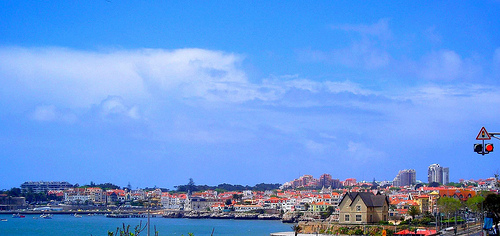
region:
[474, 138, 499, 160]
traffic light floating in the air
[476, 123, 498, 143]
traffic sign floating in the air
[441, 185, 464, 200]
red roof on old building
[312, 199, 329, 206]
red roof on old building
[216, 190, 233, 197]
red roof on old building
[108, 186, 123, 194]
red roof on old building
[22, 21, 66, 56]
white clouds in blue sky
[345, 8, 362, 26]
white clouds in blue sky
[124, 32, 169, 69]
white clouds in blue sky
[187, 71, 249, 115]
white clouds in blue sky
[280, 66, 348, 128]
white clouds in blue sky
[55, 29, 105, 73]
white clouds in blue sky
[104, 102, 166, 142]
white clouds in blue sky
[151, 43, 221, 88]
white clouds in blue sky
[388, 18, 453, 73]
white clouds in blue sky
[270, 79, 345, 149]
white clouds in blue sky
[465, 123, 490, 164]
sign on a pole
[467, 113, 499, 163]
sign on a metal pole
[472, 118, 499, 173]
pole with a sign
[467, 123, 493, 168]
metal pole with sign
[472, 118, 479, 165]
light on a pole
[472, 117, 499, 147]
light on a metal pole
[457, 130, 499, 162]
pole iwth light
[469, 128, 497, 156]
metal pole with light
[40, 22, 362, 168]
a blue sky with clouds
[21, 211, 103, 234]
a body of water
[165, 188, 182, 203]
red roof on house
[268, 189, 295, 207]
red roof on house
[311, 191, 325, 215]
red roof on house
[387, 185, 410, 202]
red roof on house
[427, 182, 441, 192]
red roof on house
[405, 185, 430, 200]
red roof on house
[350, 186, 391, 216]
black roof on house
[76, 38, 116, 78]
white clouds in blue sky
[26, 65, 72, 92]
white clouds in blue sky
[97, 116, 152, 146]
white clouds in blue sky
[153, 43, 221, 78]
a view of clouds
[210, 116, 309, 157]
a view of sky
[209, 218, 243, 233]
a view of water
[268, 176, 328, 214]
a view of buildings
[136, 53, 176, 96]
a view of clouds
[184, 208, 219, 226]
a view of ripples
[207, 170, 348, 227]
a view of houses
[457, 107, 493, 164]
a view of pole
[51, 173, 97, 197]
a view of trees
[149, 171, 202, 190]
a view of plants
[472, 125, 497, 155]
traffic signal for train crossing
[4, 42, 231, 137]
large fluffy cloud in the sky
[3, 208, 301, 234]
body of bright blue water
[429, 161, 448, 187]
skyscraper behind a bunch of smaller buildings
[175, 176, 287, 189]
a group of trees on the horizon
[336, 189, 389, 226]
tan house on the edge of the water